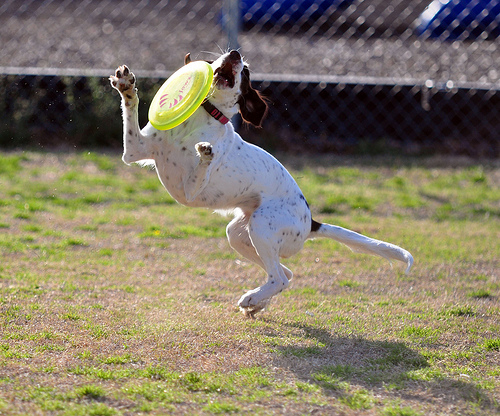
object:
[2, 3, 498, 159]
fenced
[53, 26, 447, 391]
air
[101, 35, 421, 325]
dog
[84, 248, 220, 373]
patches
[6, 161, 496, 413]
field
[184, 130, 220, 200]
leg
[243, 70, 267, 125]
ear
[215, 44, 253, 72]
nose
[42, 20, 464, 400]
day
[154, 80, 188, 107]
pattern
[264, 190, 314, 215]
spots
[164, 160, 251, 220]
chest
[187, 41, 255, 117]
face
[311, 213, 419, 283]
tail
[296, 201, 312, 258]
region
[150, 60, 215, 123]
frisbee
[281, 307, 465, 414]
shadow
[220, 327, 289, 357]
ground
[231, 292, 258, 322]
paw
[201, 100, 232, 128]
collar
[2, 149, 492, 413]
grass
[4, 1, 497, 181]
fence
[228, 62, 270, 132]
ears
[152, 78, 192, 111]
design